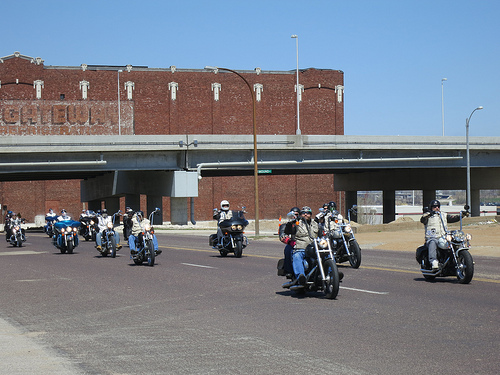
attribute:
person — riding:
[283, 205, 329, 287]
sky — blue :
[314, 25, 460, 83]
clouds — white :
[69, 18, 192, 48]